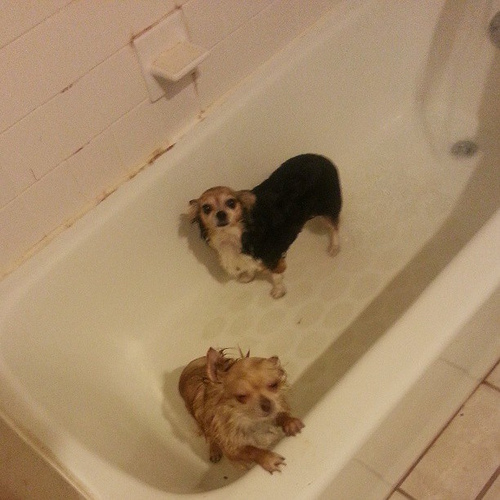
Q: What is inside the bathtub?
A: Two dogs.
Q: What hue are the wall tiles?
A: White.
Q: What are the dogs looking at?
A: The camera.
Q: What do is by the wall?
A: The Brown and black dog.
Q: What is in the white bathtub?
A: Two dogs.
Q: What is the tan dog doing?
A: Trying to climb out of the bathtub.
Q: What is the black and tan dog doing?
A: Standing in the white bathtub.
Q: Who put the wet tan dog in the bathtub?
A: Owner.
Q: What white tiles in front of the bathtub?
A: Tiles that needs grout.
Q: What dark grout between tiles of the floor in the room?
A: White grout.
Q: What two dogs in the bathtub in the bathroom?
A: Black dog and brown dog.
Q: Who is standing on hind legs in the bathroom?
A: Dog with front feet on bathtub.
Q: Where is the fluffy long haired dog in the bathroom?
A: Bathtub.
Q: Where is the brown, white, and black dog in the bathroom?
A: Middle of bathtub.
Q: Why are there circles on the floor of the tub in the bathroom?
A: Protection, from falling.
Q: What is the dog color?
A: Brown.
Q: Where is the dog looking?
A: Upward.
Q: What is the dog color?
A: Brown.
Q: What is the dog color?
A: Black.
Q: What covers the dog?
A: Water.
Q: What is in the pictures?
A: Dogs.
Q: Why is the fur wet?
A: Water.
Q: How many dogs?
A: Two.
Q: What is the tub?
A: Porcelain.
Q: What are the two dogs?
A: Canines.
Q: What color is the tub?
A: White.